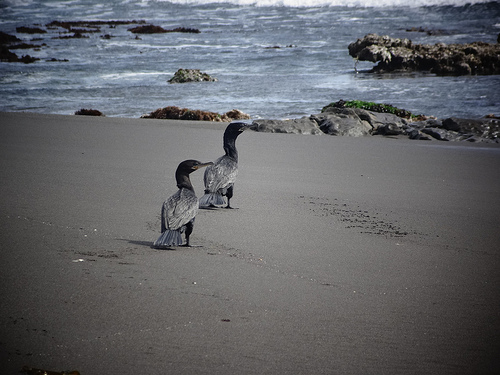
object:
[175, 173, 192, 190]
neck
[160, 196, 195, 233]
dark feathers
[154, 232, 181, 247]
dark feathers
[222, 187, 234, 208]
leg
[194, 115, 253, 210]
bird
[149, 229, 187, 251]
tail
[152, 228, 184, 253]
tail feathers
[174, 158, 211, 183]
head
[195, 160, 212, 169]
narrow beak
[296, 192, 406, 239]
marks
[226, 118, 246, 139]
head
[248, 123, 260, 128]
beak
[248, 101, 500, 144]
rock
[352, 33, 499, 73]
rock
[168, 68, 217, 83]
rock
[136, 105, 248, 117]
rock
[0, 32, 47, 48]
rock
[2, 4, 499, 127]
water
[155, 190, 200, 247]
back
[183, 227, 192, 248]
leg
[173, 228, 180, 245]
leg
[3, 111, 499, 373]
sand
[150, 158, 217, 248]
bird